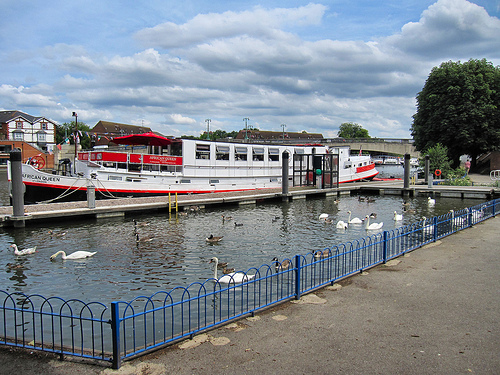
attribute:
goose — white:
[9, 242, 38, 255]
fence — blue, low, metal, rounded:
[1, 198, 499, 369]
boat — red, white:
[0, 180, 499, 228]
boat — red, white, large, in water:
[7, 138, 380, 195]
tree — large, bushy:
[410, 57, 500, 173]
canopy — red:
[113, 131, 173, 147]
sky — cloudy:
[0, 0, 499, 140]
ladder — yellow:
[167, 192, 179, 213]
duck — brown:
[205, 234, 224, 242]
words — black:
[21, 172, 62, 183]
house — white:
[0, 110, 57, 154]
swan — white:
[50, 250, 98, 261]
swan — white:
[208, 257, 256, 284]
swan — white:
[448, 209, 464, 225]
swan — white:
[420, 216, 435, 234]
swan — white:
[347, 210, 365, 225]